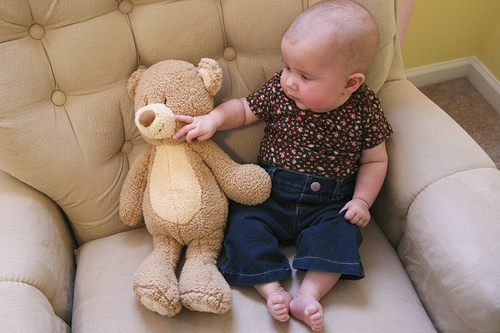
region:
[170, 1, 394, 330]
baby touching teddy bear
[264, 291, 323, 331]
baby's curling toes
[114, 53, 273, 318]
soft brown teddy bear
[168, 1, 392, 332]
baby wearing flowered shirt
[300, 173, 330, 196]
silver button on denim pants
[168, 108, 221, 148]
baby's hand on teddy bear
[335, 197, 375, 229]
baby's hand holding pants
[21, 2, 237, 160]
tan buttons on armchair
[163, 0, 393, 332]
baby in denim pants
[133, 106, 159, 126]
brown teddy bear nose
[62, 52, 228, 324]
teddy bear is brown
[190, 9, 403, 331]
a baby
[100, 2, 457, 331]
a baby and a teddy bear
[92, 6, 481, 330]
a baby touches a teddy bear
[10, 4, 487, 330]
a baby with a teddy bear sit in a plush chair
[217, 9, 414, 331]
the baby has no shoes on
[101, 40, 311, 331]
the bear is tan with a lighter colored belly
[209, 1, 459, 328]
the baby is touching the bear's face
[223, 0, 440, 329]
the baby is wearing jeans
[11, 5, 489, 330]
the chair is tan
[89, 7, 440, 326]
a baby and teddy bear sit together in a chair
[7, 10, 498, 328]
Indoor view of furniture and occupants.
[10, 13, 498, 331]
Large, plush, buff chair.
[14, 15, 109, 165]
Quilting on chair.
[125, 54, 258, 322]
Floppy, stuffed brown bear,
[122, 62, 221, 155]
Bear head, facing left.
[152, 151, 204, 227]
Pale, bear tummy.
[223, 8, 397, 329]
Pink, bald baby in print shirt an djeans.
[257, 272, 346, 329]
Bare, baby feet.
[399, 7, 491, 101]
White baseboard and yellow paint on wall corner.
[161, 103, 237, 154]
Baby hand, touching bear face.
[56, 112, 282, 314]
chair is brown and plush